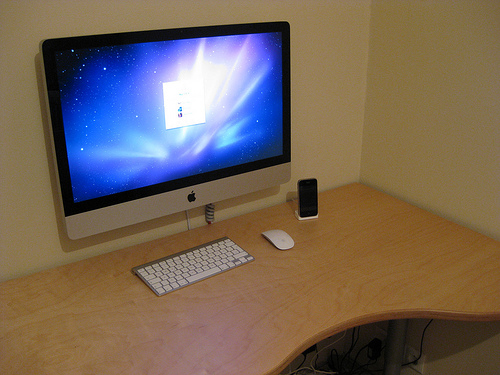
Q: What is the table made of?
A: Wood.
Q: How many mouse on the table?
A: One.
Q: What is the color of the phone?
A: Black.